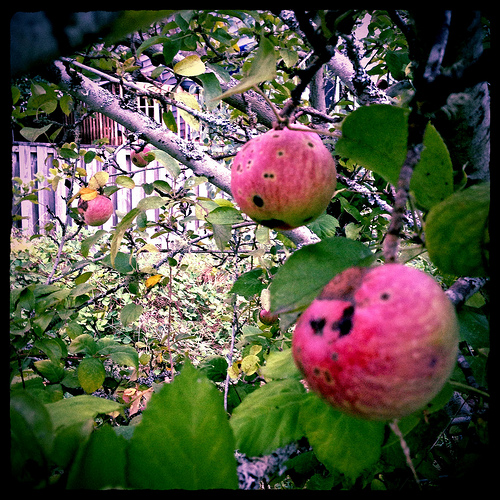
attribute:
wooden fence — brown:
[9, 135, 234, 242]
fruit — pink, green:
[229, 124, 339, 233]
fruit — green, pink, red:
[291, 262, 458, 417]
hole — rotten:
[246, 190, 266, 206]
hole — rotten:
[298, 305, 363, 338]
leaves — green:
[10, 261, 153, 389]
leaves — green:
[23, 101, 491, 474]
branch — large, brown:
[25, 58, 327, 247]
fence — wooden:
[13, 145, 73, 222]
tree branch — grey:
[39, 58, 322, 246]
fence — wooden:
[12, 141, 279, 241]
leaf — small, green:
[234, 374, 304, 452]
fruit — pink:
[304, 257, 459, 408]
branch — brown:
[56, 76, 256, 176]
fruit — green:
[234, 118, 336, 235]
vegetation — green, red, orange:
[133, 278, 193, 335]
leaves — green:
[37, 297, 247, 483]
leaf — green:
[126, 352, 238, 490]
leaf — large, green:
[66, 328, 140, 388]